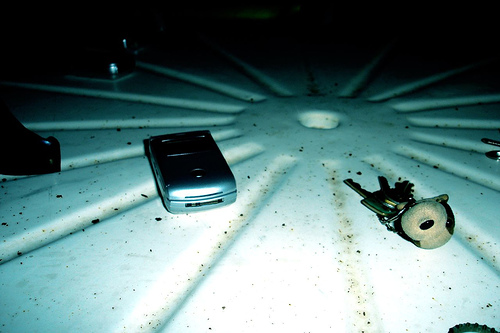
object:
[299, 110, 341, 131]
hole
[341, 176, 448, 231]
key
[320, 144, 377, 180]
specks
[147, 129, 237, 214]
cell phone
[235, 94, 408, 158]
flatbread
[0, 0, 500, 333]
indentions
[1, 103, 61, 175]
black object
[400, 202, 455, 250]
key chain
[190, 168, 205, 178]
circle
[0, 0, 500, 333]
table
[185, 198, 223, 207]
charging port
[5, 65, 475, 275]
surface